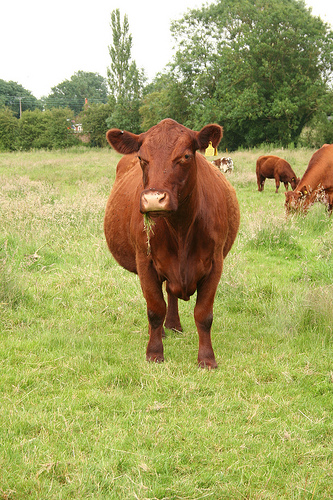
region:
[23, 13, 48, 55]
white clouds in blue sky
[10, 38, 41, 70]
white clouds in blue sky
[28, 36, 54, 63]
white clouds in blue sky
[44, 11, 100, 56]
white clouds in blue sky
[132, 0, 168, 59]
white clouds in blue sky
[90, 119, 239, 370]
dark brown cow in field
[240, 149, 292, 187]
dark brown cow in field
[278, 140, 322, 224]
dark brown cow in field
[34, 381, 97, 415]
short green and yellow grass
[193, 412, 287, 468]
short green and yellow grass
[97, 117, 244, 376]
brown cow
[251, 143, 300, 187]
brown cow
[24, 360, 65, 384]
short yellow and green grass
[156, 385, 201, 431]
short yellow and green grass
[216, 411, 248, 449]
short yellow and green grass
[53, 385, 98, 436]
short yellow and green grass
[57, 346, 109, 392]
short yellow and green grass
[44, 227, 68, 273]
short yellow and green grass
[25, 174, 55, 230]
short yellow and green grass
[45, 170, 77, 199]
short yellow and green grass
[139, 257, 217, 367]
The front legs of the cow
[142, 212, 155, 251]
Grass in the cow's mouth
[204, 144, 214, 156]
A tag on the cow's ear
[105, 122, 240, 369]
A brown cow in the grass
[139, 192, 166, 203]
The nose of the cow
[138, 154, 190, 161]
The eyes of the cow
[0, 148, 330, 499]
The grass below the cows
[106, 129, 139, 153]
The right ear of the cow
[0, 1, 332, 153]
Trees behind the cows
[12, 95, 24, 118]
A telephone pole by the trees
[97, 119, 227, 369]
brown cow standing in the grass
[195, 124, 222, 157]
cow's ear with a yellow identification tag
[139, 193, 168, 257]
grass hanging out of the brown cow's mouth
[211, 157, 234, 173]
brown and white cow in the background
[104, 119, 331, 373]
cattle grazing in a field of grass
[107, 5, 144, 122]
tall skinny tree in the background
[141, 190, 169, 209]
cow's pink nose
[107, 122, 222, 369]
brown cow looking toward the camera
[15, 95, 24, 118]
telephone pole behind the trees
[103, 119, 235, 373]
brown cow standing in the green grass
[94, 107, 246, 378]
a cow on a green field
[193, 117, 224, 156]
right ear of cow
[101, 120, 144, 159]
left ear of cow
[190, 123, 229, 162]
a yellow tag on right ear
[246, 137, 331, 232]
a cow eating grass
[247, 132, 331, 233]
two brown cows eating grass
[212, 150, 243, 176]
a white and brown cow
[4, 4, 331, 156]
green trees behind a cow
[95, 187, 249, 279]
belly of cow is bulky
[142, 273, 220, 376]
front legs of cow